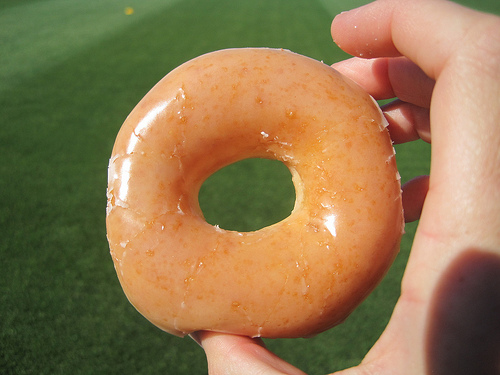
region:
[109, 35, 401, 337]
this is a doughnut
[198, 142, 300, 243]
this is a hole in a doughnut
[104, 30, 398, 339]
this is a round doughnut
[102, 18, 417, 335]
this is a brown doughnut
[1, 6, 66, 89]
this is green vegetation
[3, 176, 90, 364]
this is green vegetation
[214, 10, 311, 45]
this is green vegetation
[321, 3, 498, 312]
these are fingers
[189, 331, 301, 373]
this is a finger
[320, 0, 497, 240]
these are four fingers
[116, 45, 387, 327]
this is a doughnurt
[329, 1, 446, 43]
this is a finger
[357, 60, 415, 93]
this is a finger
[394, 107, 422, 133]
this is a finger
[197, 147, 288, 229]
this is a hole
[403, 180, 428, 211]
this is a finger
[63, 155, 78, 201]
the grass is fresh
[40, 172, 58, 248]
the grass is fresh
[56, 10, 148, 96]
the grass is fresh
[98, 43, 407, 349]
A glazed donut held up in mid air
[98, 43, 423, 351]
A held up glazed donut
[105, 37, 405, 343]
doughnut with hole in middle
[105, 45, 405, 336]
brown doughnut with white sugar coating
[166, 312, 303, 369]
thumb press into a doughnut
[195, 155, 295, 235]
oval shaped doughnut hole in center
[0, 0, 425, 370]
green grass covering ground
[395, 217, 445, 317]
pink lines on pale hand skin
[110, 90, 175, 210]
arc of light on top of doughnut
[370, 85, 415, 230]
flakes of sugar icing on side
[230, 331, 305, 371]
slight ridge along thumb